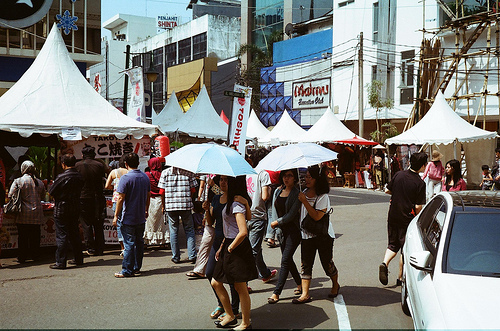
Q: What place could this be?
A: It is a street.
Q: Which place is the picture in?
A: It is at the street.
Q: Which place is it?
A: It is a street.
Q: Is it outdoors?
A: Yes, it is outdoors.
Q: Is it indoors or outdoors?
A: It is outdoors.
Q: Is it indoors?
A: No, it is outdoors.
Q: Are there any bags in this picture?
A: Yes, there is a bag.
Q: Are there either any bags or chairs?
A: Yes, there is a bag.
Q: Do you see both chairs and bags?
A: No, there is a bag but no chairs.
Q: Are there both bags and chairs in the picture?
A: No, there is a bag but no chairs.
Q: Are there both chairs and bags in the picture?
A: No, there is a bag but no chairs.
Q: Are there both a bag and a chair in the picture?
A: No, there is a bag but no chairs.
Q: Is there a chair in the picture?
A: No, there are no chairs.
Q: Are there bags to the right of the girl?
A: Yes, there is a bag to the right of the girl.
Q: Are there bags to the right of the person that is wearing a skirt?
A: Yes, there is a bag to the right of the girl.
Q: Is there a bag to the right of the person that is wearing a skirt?
A: Yes, there is a bag to the right of the girl.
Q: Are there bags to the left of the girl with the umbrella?
A: No, the bag is to the right of the girl.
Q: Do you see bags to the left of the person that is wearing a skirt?
A: No, the bag is to the right of the girl.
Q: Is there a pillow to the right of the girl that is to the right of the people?
A: No, there is a bag to the right of the girl.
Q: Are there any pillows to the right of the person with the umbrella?
A: No, there is a bag to the right of the girl.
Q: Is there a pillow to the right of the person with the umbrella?
A: No, there is a bag to the right of the girl.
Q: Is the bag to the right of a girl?
A: Yes, the bag is to the right of a girl.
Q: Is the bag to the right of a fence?
A: No, the bag is to the right of a girl.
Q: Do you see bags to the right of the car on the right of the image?
A: No, the bag is to the left of the car.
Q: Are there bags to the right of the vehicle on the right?
A: No, the bag is to the left of the car.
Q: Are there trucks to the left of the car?
A: No, there is a bag to the left of the car.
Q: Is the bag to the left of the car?
A: Yes, the bag is to the left of the car.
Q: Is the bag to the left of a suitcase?
A: No, the bag is to the left of the car.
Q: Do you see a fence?
A: No, there are no fences.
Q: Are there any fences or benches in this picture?
A: No, there are no fences or benches.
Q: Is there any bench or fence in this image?
A: No, there are no fences or benches.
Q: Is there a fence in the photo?
A: No, there are no fences.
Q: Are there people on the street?
A: Yes, there are people on the street.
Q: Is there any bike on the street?
A: No, there are people on the street.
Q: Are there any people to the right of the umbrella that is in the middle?
A: No, the people are to the left of the umbrella.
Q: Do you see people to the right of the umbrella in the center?
A: No, the people are to the left of the umbrella.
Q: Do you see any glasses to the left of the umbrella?
A: No, there are people to the left of the umbrella.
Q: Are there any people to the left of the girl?
A: Yes, there are people to the left of the girl.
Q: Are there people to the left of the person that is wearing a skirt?
A: Yes, there are people to the left of the girl.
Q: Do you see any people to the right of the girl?
A: No, the people are to the left of the girl.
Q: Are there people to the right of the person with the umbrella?
A: No, the people are to the left of the girl.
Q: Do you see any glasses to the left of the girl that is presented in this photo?
A: No, there are people to the left of the girl.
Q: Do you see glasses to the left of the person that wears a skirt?
A: No, there are people to the left of the girl.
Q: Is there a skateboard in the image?
A: No, there are no skateboards.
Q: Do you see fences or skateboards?
A: No, there are no skateboards or fences.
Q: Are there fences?
A: No, there are no fences.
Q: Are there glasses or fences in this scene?
A: No, there are no fences or glasses.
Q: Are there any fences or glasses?
A: No, there are no fences or glasses.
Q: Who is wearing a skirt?
A: The girl is wearing a skirt.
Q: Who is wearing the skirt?
A: The girl is wearing a skirt.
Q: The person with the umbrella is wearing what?
A: The girl is wearing a skirt.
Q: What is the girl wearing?
A: The girl is wearing a skirt.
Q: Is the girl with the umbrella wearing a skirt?
A: Yes, the girl is wearing a skirt.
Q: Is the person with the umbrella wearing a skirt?
A: Yes, the girl is wearing a skirt.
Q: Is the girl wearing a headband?
A: No, the girl is wearing a skirt.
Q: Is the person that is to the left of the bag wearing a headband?
A: No, the girl is wearing a skirt.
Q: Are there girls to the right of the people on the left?
A: Yes, there is a girl to the right of the people.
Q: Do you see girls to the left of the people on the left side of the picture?
A: No, the girl is to the right of the people.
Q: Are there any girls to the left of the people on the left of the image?
A: No, the girl is to the right of the people.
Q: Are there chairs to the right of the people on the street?
A: No, there is a girl to the right of the people.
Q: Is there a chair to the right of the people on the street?
A: No, there is a girl to the right of the people.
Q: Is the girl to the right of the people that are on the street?
A: Yes, the girl is to the right of the people.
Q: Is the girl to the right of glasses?
A: No, the girl is to the right of the people.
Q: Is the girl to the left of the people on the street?
A: No, the girl is to the right of the people.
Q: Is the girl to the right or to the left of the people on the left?
A: The girl is to the right of the people.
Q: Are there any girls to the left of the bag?
A: Yes, there is a girl to the left of the bag.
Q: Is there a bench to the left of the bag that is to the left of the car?
A: No, there is a girl to the left of the bag.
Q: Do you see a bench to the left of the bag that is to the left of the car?
A: No, there is a girl to the left of the bag.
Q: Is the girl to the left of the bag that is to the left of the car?
A: Yes, the girl is to the left of the bag.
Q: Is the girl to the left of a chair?
A: No, the girl is to the left of the bag.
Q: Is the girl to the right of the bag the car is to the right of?
A: No, the girl is to the left of the bag.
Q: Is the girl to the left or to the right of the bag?
A: The girl is to the left of the bag.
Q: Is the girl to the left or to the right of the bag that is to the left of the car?
A: The girl is to the left of the bag.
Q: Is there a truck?
A: No, there are no trucks.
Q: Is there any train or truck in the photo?
A: No, there are no trucks or trains.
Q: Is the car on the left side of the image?
A: No, the car is on the right of the image.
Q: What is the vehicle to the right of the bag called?
A: The vehicle is a car.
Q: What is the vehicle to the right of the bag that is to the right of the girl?
A: The vehicle is a car.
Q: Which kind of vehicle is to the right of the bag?
A: The vehicle is a car.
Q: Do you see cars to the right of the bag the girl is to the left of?
A: Yes, there is a car to the right of the bag.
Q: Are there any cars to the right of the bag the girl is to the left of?
A: Yes, there is a car to the right of the bag.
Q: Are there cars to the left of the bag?
A: No, the car is to the right of the bag.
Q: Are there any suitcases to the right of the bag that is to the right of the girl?
A: No, there is a car to the right of the bag.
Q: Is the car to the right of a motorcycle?
A: No, the car is to the right of a bag.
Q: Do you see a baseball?
A: No, there are no baseballs.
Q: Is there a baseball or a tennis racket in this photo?
A: No, there are no baseballs or rackets.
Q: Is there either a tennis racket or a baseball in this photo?
A: No, there are no baseballs or rackets.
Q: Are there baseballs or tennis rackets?
A: No, there are no baseballs or tennis rackets.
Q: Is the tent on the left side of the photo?
A: Yes, the tent is on the left of the image.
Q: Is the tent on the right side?
A: No, the tent is on the left of the image.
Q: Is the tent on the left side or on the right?
A: The tent is on the left of the image.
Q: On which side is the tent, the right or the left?
A: The tent is on the left of the image.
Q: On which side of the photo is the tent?
A: The tent is on the left of the image.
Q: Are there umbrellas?
A: Yes, there is an umbrella.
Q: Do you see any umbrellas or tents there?
A: Yes, there is an umbrella.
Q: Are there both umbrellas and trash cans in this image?
A: No, there is an umbrella but no trash cans.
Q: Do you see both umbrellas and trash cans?
A: No, there is an umbrella but no trash cans.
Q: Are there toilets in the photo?
A: No, there are no toilets.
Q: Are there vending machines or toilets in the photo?
A: No, there are no toilets or vending machines.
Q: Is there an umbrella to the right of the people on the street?
A: Yes, there is an umbrella to the right of the people.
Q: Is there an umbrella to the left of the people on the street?
A: No, the umbrella is to the right of the people.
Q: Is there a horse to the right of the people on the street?
A: No, there is an umbrella to the right of the people.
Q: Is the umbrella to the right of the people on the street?
A: Yes, the umbrella is to the right of the people.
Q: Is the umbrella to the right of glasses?
A: No, the umbrella is to the right of the people.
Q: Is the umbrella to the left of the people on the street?
A: No, the umbrella is to the right of the people.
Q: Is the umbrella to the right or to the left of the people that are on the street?
A: The umbrella is to the right of the people.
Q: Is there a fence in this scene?
A: No, there are no fences.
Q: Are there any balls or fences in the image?
A: No, there are no fences or balls.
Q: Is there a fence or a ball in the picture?
A: No, there are no fences or balls.